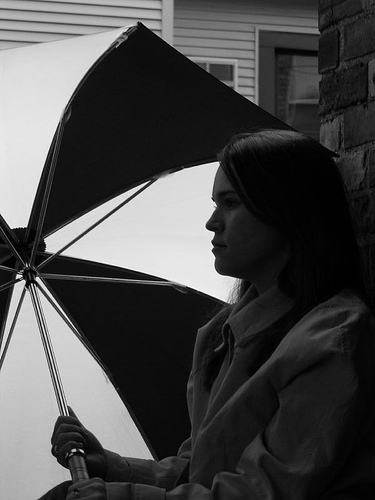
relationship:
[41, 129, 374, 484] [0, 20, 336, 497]
woman holding umbrella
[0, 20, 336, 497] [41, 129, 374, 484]
umbrella at side of woman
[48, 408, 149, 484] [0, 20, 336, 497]
hand around umbrella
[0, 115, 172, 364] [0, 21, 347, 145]
rods are pointing outwards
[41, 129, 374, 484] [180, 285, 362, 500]
woman have raincoat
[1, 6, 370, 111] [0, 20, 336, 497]
house behind umbrella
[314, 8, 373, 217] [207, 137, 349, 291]
wall behind head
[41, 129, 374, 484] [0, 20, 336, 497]
woman have umbrella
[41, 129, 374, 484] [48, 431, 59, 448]
woman have a ring on her finger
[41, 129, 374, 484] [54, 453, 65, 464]
woman have a ring on her finger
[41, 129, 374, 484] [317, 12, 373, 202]
woman against bricks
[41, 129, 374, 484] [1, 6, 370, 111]
woman close to house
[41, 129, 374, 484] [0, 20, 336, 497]
woman holding an umbrella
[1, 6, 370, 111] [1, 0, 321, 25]
house have shingles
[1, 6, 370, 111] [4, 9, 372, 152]
house in backround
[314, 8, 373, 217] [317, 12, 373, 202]
wall have bricks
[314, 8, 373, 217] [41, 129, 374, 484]
wall behind woman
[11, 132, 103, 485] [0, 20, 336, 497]
spoke on umbrella